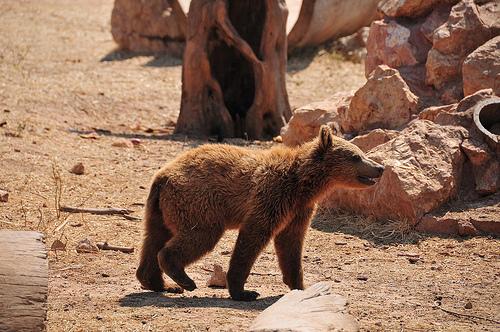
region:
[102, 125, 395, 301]
baby bear in the photo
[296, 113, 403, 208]
head of the bear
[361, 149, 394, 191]
nose of the bear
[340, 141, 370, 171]
eye of the bear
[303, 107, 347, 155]
ear of the bear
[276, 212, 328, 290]
front leg of bear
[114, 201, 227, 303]
back legs of the bear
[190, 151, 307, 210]
brown fur on bear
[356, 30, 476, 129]
rocks next to the bear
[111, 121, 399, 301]
a young bear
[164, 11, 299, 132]
an old hollowed-out tree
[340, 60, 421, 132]
a large rock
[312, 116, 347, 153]
the ears of a young bear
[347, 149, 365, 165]
the eye of a young bear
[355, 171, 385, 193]
the mouth of a young bear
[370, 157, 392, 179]
the nose of a young bear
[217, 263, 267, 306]
the front paw of a young bear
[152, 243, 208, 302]
the back foot of a young bear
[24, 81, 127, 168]
some dirt on the ground of a bear den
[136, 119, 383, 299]
brown bear walking on dirt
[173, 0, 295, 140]
hollow tree stump in bear exhibit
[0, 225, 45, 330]
log sitting on ground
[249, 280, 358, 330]
piece of wood sitting on ground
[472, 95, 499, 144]
circular object surrounded by rocks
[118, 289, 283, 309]
shadow of bear on ground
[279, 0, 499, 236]
red rocks in a bear exhibit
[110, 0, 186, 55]
log sitting on ground of bear exhibit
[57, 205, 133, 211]
stick sitting on ground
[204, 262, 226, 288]
rock sitting on ground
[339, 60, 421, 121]
rock in rock pile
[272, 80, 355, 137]
rock in rock pile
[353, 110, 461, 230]
rock in rock pile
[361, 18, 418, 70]
rock in rock pile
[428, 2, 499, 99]
rocks in rock pile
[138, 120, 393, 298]
bear cub walking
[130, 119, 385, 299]
bear cub walking past rock pile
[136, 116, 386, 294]
bear cub walking on the ground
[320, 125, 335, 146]
ear on the bed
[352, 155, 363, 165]
eye on the bear cub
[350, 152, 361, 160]
eye of a bear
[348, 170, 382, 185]
mouth of a bear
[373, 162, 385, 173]
nose of a bear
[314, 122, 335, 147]
ear of a bear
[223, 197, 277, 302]
leg of a bear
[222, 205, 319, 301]
two legs of a cub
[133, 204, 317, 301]
four legs of a bear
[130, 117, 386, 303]
brown cub walking on a dirt ground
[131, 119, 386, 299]
cub with one of its legs off the ground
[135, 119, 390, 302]
lone bear on a dirt ground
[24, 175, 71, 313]
Large wooden log behind the bear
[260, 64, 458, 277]
Large log to the left of the bear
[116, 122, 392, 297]
Big bear is brown in color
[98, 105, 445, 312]
Brown bear is looking to the right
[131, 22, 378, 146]
Large stump in the middle of the dirt cage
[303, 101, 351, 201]
Ears of the bear are sticking up in the air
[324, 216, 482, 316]
Gras and sticks on the ground in front of the bear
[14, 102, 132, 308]
Large sticks and grass behind the bear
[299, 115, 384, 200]
the head of a bear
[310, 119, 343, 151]
the ear of a bear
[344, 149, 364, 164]
the eye of a bear